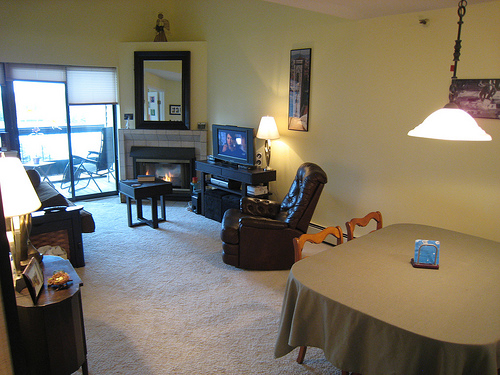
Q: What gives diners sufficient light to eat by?
A: Hanging lights above the table.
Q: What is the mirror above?
A: The fireplace.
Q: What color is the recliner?
A: Brown.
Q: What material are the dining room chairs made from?
A: Wood.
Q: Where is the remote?
A: Arm of couch.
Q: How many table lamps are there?
A: 2.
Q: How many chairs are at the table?
A: 2.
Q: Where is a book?
A: Coffee table.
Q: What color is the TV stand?
A: Black.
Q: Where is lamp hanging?
A: Above the table.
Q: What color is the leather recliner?
A: Black.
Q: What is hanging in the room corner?
A: Mirror.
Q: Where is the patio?
A: Behind the sliding door.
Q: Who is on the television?
A: A male face.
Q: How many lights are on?
A: 3.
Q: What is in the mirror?
A: A reflection.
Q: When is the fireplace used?
A: Now.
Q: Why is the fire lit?
A: It is cold outside.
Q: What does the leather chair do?
A: It reclines.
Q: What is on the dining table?
A: A tablecloth.